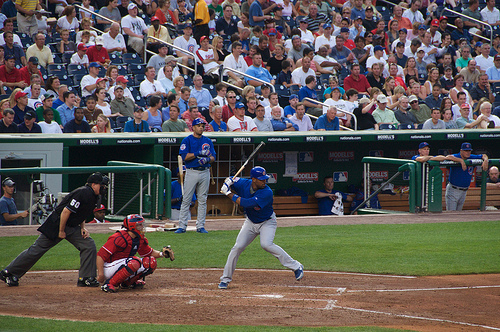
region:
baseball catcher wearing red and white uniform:
[94, 204, 166, 295]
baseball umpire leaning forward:
[9, 162, 99, 301]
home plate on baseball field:
[246, 280, 286, 308]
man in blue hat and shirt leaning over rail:
[445, 140, 485, 207]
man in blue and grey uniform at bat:
[216, 136, 311, 298]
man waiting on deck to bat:
[171, 109, 221, 245]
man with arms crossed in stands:
[269, 105, 297, 132]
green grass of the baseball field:
[303, 225, 431, 268]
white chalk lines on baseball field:
[326, 283, 440, 300]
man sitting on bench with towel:
[314, 174, 353, 216]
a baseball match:
[5, 7, 499, 329]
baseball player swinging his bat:
[206, 133, 321, 308]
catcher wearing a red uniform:
[100, 200, 180, 299]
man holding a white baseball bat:
[174, 155, 191, 198]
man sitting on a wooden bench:
[302, 169, 355, 220]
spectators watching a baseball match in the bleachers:
[10, 1, 487, 131]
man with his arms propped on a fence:
[447, 137, 499, 210]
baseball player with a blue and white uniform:
[213, 166, 305, 303]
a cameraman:
[1, 172, 66, 226]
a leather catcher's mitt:
[158, 240, 180, 267]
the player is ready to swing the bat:
[27, 106, 319, 293]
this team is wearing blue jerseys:
[221, 157, 278, 241]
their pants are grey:
[213, 212, 319, 290]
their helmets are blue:
[182, 112, 269, 188]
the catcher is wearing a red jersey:
[76, 196, 182, 313]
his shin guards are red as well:
[108, 198, 182, 313]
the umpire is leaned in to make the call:
[14, 163, 121, 318]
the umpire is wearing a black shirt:
[54, 151, 111, 293]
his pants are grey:
[19, 206, 113, 309]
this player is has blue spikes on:
[165, 217, 215, 244]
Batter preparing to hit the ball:
[200, 137, 310, 287]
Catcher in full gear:
[92, 207, 174, 292]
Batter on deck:
[172, 116, 214, 238]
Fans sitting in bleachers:
[5, 50, 235, 135]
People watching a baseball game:
[335, 50, 495, 130]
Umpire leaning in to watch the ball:
[0, 173, 110, 295]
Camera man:
[0, 172, 55, 227]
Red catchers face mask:
[116, 211, 161, 241]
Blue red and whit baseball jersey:
[173, 132, 217, 167]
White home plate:
[229, 278, 301, 308]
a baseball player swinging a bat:
[217, 137, 318, 291]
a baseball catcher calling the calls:
[97, 203, 182, 295]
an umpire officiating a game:
[1, 155, 113, 287]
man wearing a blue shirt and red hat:
[11, 87, 41, 124]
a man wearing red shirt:
[344, 61, 374, 95]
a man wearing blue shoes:
[201, 147, 311, 298]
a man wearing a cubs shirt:
[171, 19, 200, 64]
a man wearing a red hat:
[426, 17, 446, 50]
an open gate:
[111, 151, 446, 221]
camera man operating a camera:
[2, 175, 69, 225]